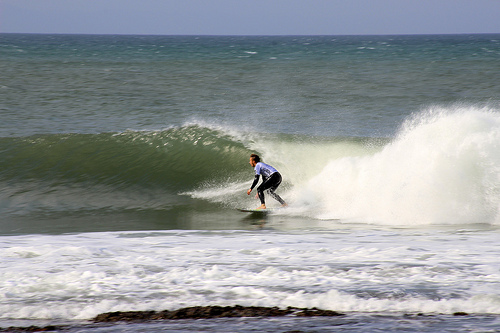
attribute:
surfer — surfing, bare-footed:
[245, 154, 290, 213]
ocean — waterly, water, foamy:
[1, 1, 497, 307]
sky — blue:
[0, 1, 499, 35]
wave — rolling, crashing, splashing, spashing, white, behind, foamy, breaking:
[2, 121, 498, 215]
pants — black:
[257, 172, 287, 205]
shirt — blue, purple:
[247, 163, 278, 188]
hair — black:
[249, 154, 260, 163]